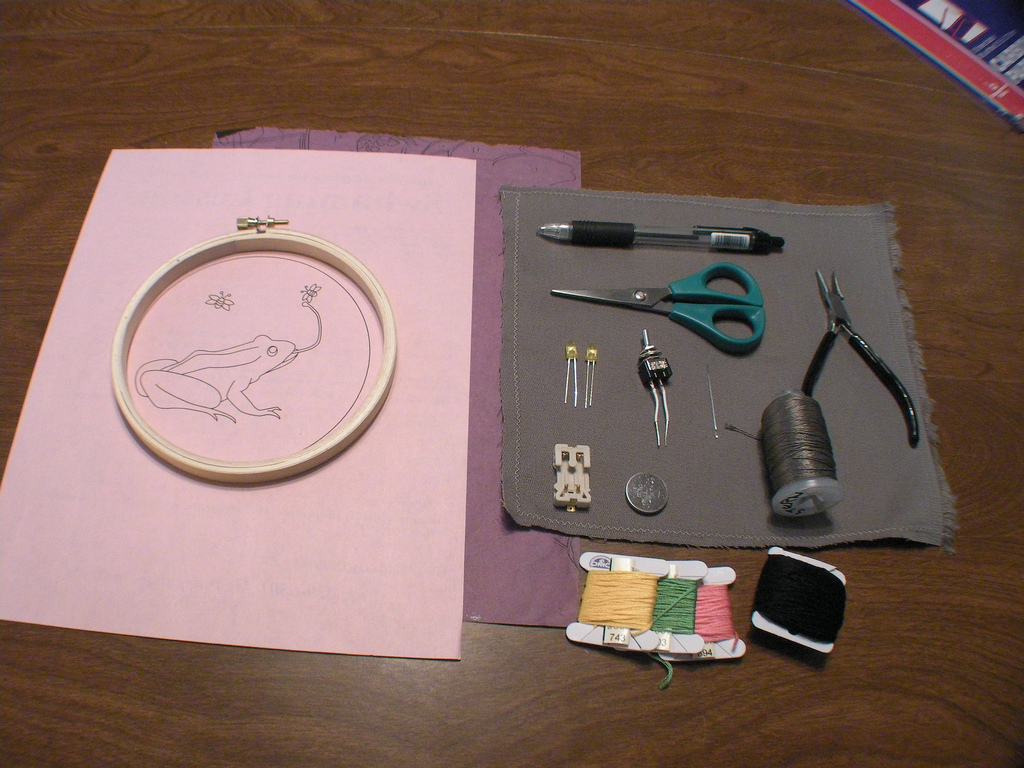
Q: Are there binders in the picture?
A: No, there are no binders.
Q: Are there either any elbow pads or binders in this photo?
A: No, there are no binders or elbow pads.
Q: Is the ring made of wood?
A: Yes, the ring is made of wood.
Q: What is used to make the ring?
A: The ring is made of wood.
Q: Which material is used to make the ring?
A: The ring is made of wood.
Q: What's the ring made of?
A: The ring is made of wood.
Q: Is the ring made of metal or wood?
A: The ring is made of wood.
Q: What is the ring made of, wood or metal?
A: The ring is made of wood.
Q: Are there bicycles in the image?
A: No, there are no bicycles.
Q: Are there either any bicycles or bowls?
A: No, there are no bicycles or bowls.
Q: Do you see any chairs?
A: No, there are no chairs.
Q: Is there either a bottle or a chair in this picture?
A: No, there are no chairs or bottles.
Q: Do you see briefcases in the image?
A: No, there are no briefcases.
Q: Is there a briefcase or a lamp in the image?
A: No, there are no briefcases or lamps.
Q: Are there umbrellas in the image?
A: No, there are no umbrellas.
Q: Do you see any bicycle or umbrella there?
A: No, there are no umbrellas or bicycles.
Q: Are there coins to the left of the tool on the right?
A: Yes, there is a coin to the left of the tool.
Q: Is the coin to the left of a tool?
A: Yes, the coin is to the left of a tool.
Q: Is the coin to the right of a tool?
A: Yes, the coin is to the right of a tool.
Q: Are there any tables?
A: Yes, there is a table.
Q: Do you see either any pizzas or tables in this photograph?
A: Yes, there is a table.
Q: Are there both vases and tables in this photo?
A: No, there is a table but no vases.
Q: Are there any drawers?
A: No, there are no drawers.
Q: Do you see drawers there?
A: No, there are no drawers.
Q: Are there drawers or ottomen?
A: No, there are no drawers or ottomen.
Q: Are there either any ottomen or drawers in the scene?
A: No, there are no drawers or ottomen.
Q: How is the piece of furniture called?
A: The piece of furniture is a table.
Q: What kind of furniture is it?
A: The piece of furniture is a table.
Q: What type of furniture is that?
A: That is a table.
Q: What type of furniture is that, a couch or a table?
A: That is a table.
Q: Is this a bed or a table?
A: This is a table.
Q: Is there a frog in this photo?
A: Yes, there is a frog.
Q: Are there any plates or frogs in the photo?
A: Yes, there is a frog.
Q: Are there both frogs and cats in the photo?
A: No, there is a frog but no cats.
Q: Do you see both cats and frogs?
A: No, there is a frog but no cats.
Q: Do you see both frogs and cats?
A: No, there is a frog but no cats.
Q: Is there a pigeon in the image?
A: No, there are no pigeons.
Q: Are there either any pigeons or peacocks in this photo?
A: No, there are no pigeons or peacocks.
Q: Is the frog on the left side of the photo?
A: Yes, the frog is on the left of the image.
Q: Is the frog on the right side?
A: No, the frog is on the left of the image.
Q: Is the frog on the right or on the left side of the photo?
A: The frog is on the left of the image.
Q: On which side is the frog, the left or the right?
A: The frog is on the left of the image.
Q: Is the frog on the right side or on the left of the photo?
A: The frog is on the left of the image.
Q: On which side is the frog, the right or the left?
A: The frog is on the left of the image.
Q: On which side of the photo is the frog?
A: The frog is on the left of the image.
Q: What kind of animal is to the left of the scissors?
A: The animal is a frog.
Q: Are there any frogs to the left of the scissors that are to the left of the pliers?
A: Yes, there is a frog to the left of the scissors.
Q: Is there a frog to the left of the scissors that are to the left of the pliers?
A: Yes, there is a frog to the left of the scissors.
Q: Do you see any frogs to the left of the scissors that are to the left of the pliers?
A: Yes, there is a frog to the left of the scissors.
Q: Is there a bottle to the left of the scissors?
A: No, there is a frog to the left of the scissors.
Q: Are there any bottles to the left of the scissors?
A: No, there is a frog to the left of the scissors.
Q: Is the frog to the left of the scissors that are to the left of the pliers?
A: Yes, the frog is to the left of the scissors.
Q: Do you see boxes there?
A: No, there are no boxes.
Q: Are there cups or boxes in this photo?
A: No, there are no boxes or cups.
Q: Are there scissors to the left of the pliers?
A: Yes, there are scissors to the left of the pliers.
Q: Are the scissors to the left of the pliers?
A: Yes, the scissors are to the left of the pliers.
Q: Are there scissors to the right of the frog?
A: Yes, there are scissors to the right of the frog.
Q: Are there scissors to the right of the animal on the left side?
A: Yes, there are scissors to the right of the frog.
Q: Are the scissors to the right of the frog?
A: Yes, the scissors are to the right of the frog.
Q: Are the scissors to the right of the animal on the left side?
A: Yes, the scissors are to the right of the frog.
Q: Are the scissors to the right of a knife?
A: No, the scissors are to the right of the frog.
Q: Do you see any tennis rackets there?
A: No, there are no tennis rackets.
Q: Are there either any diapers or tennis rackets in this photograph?
A: No, there are no tennis rackets or diapers.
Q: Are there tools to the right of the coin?
A: Yes, there is a tool to the right of the coin.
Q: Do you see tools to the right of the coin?
A: Yes, there is a tool to the right of the coin.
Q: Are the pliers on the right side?
A: Yes, the pliers are on the right of the image.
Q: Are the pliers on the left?
A: No, the pliers are on the right of the image.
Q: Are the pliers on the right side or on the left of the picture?
A: The pliers are on the right of the image.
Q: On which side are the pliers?
A: The pliers are on the right of the image.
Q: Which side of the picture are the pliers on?
A: The pliers are on the right of the image.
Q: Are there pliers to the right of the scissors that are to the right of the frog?
A: Yes, there are pliers to the right of the scissors.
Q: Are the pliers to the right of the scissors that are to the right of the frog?
A: Yes, the pliers are to the right of the scissors.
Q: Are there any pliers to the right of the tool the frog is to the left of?
A: Yes, there are pliers to the right of the tool.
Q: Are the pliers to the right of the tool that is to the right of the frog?
A: Yes, the pliers are to the right of the tool.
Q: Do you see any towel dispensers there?
A: No, there are no towel dispensers.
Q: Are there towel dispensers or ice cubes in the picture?
A: No, there are no towel dispensers or ice cubes.